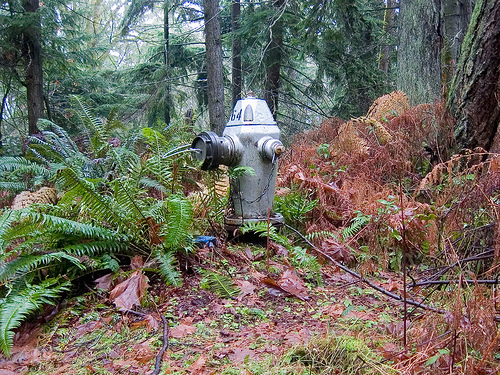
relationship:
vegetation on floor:
[322, 330, 368, 355] [115, 303, 294, 349]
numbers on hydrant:
[224, 102, 243, 125] [183, 92, 299, 246]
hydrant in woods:
[183, 92, 299, 246] [2, 1, 499, 284]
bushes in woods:
[0, 90, 500, 358] [2, 1, 499, 284]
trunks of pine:
[199, 0, 233, 120] [328, 12, 385, 102]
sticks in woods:
[138, 304, 177, 375] [2, 1, 499, 284]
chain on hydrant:
[256, 159, 280, 210] [183, 92, 299, 246]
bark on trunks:
[207, 55, 218, 78] [199, 0, 233, 120]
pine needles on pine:
[346, 25, 368, 39] [328, 12, 385, 102]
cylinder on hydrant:
[190, 126, 236, 183] [183, 92, 299, 246]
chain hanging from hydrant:
[256, 159, 280, 210] [183, 92, 299, 246]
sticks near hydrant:
[138, 304, 177, 375] [183, 92, 299, 246]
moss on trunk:
[465, 18, 476, 54] [453, 3, 489, 155]